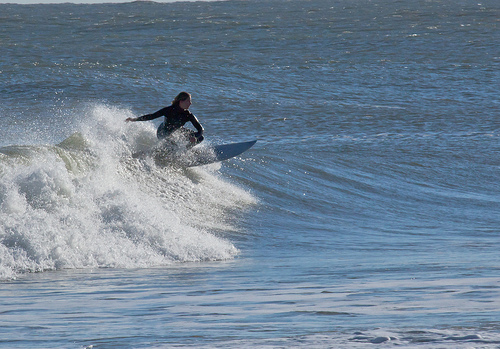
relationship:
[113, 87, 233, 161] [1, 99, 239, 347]
surfer at side of white wave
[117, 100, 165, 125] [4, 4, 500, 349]
arm swung back with hand in ocean water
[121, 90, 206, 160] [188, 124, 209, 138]
surfer looking forward with bent elbow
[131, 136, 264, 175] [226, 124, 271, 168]
surfboard tipping up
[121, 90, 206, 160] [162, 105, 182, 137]
surfer wearing dark wetsuit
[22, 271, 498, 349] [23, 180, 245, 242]
water in front of wave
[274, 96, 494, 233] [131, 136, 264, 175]
curve of blue water toward surfboard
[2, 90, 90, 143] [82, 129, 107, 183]
drops of water behind wave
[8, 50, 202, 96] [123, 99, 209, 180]
lighter blue curve of water behind surfer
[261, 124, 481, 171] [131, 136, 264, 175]
line of water to side of surfboard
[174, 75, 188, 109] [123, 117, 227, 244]
hair of lady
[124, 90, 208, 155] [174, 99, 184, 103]
person has brown hair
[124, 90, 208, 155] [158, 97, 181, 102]
person has long hair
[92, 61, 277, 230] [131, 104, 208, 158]
person wearing wetsuit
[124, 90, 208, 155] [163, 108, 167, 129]
person wetsuit black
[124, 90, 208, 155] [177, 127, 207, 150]
person has leg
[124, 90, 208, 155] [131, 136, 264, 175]
person standing on surfboard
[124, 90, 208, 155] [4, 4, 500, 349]
person surfing in ocean water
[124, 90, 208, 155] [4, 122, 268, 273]
person riding wave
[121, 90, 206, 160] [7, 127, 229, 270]
surfer riding wave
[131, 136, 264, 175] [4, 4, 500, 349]
surfboard in ocean water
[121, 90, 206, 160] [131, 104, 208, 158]
surfer wearing wetsuit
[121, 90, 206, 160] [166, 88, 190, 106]
surfer has hair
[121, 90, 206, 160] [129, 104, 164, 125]
surfer has arm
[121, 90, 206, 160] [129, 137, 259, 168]
surfer crouching on board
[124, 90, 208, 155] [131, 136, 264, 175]
person on surfboard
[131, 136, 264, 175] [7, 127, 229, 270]
surfboard on wave